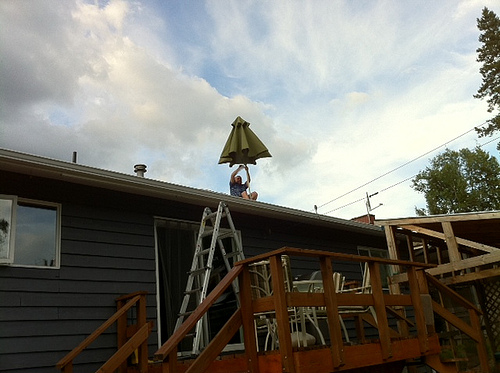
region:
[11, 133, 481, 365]
This is a building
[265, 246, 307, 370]
This is a pole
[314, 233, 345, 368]
This is a pole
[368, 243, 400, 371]
This is a pole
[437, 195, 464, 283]
This is a pole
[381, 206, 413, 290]
This is a pole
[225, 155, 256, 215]
This is a man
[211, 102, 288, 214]
This is an umbrella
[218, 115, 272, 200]
person holding an umbrella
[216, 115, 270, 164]
umbrella canopy is green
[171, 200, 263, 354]
gray metal ladder on deck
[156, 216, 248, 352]
sliding door behind ladder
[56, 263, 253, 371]
handrail attached to deck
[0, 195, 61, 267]
window to the left of deck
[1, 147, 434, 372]
house is sided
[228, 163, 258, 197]
person on top of house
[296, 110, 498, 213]
power lines behind house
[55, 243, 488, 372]
deck is stained brown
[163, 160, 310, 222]
man sits on a roof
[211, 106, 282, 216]
man holds a parasol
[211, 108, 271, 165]
parasol is green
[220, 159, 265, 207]
man wears blue shirt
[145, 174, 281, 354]
a ladder below a roof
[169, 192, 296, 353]
ladder is color white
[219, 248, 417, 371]
furniture over a deck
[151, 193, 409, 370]
a ladder on a deck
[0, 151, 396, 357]
a home color gray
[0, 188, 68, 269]
window has white frame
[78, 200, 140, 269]
this is a house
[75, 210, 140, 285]
the wall is grey in color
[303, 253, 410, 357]
this is the balcon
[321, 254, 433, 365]
the balcon is wooden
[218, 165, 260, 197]
this is a man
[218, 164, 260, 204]
the man is sitted on the roof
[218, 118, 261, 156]
this is an umbrella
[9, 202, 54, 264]
this is the window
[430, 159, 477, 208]
the leaves are green in color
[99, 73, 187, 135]
the clouds are above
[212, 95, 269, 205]
man holding a patio umbrella on roof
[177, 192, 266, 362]
ladder on a back porch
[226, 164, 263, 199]
man sitting on top of a house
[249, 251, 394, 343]
outdoor furniature on back patio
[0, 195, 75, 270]
window on a house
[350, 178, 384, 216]
power line pole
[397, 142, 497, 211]
tree reaching the powerlines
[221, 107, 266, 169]
a large patio type umbrella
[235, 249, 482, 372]
railing on a back deck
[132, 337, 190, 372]
patio stairs made of wood